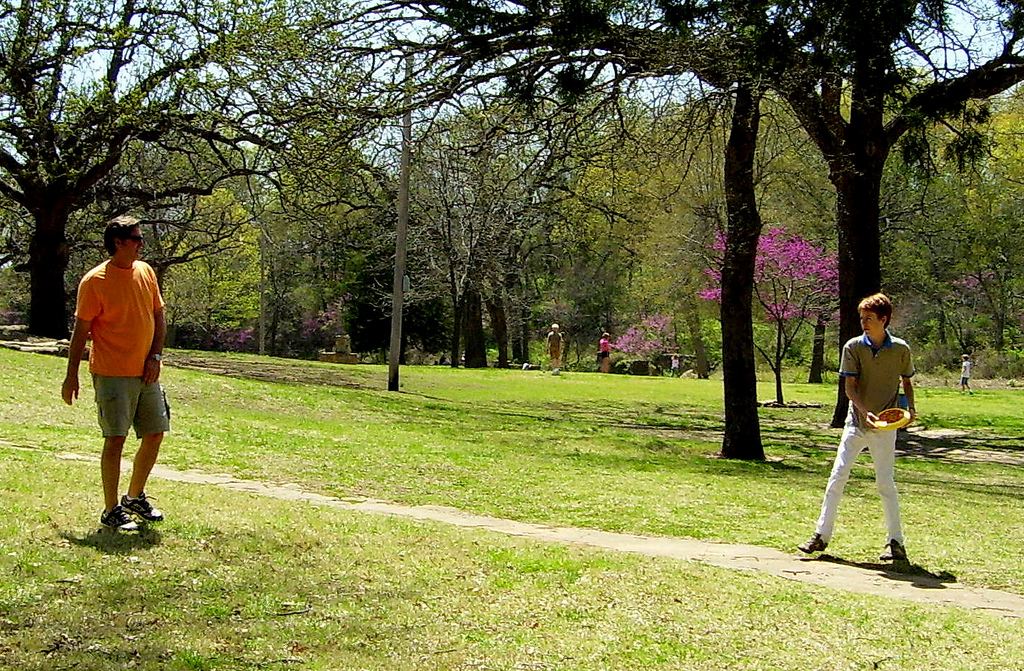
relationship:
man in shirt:
[40, 223, 274, 507] [51, 258, 235, 431]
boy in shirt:
[792, 290, 918, 565] [817, 329, 978, 479]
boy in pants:
[766, 257, 939, 543] [777, 435, 942, 591]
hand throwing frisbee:
[855, 404, 879, 430] [866, 405, 908, 434]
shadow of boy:
[831, 547, 957, 606] [792, 290, 918, 565]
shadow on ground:
[831, 547, 957, 606] [8, 327, 992, 656]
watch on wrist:
[144, 338, 171, 360] [134, 340, 167, 369]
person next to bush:
[587, 325, 622, 380] [609, 314, 694, 379]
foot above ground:
[795, 532, 835, 556] [747, 504, 901, 662]